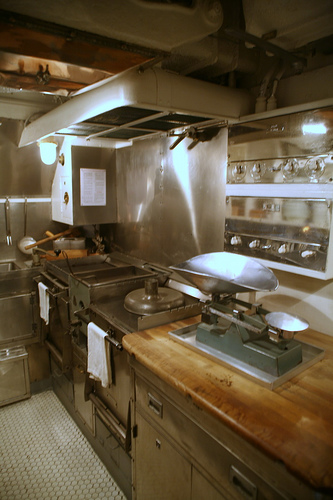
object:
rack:
[72, 304, 125, 350]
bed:
[168, 249, 279, 299]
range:
[53, 105, 215, 154]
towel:
[37, 281, 52, 328]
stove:
[38, 256, 74, 419]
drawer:
[137, 379, 274, 499]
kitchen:
[0, 0, 333, 500]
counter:
[122, 290, 333, 448]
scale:
[165, 248, 310, 378]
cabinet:
[116, 302, 315, 500]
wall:
[0, 164, 44, 194]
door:
[131, 407, 191, 498]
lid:
[122, 278, 186, 318]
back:
[118, 126, 228, 284]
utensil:
[5, 198, 14, 247]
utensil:
[17, 197, 40, 256]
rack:
[0, 196, 52, 204]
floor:
[0, 416, 82, 498]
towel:
[86, 321, 113, 390]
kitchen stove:
[69, 250, 200, 489]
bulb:
[38, 138, 58, 166]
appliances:
[62, 277, 180, 407]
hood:
[15, 76, 247, 154]